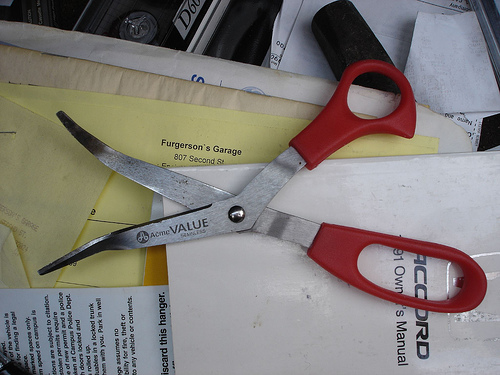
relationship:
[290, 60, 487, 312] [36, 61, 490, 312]
handles of scissors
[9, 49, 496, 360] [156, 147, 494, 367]
scissors on paper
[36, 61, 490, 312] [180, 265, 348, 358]
scissors on manual